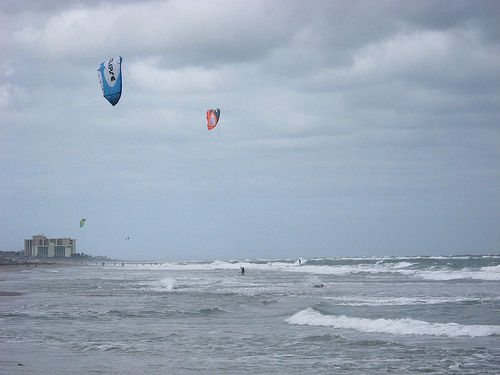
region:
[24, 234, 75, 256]
building in the background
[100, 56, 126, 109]
blue hang gliding kite in the sky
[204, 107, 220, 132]
orange and black hang gliding kite in the sky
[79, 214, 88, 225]
bright green hang gliding kite in the sky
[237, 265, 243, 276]
person hang gliding over the ocean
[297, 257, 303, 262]
person surfing on the huge waves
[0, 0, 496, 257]
the sky contains heavy clouds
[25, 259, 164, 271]
people standing near the shore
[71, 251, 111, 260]
trees near the huge building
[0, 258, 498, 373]
clean water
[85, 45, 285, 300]
large kites flying over the ocean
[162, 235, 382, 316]
person standing in a vast ocean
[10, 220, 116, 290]
large tan building near the beach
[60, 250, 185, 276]
people along the shore at a distance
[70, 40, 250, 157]
grey clouds and sky behind kites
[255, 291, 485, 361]
low wave edged in white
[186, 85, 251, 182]
red and grey kite in a triangular shape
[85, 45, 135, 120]
blue and white kite with point at bottom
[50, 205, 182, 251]
kites flying farther down beach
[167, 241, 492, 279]
horizon of grey and white waves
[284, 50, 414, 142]
part of a cloudy sky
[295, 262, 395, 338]
part of an ocean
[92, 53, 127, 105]
part of a blue kite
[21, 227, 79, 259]
section of some buildings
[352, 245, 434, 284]
part of some currents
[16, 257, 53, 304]
part of the shore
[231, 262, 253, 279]
a person in black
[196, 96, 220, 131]
part of a red kite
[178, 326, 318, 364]
part of some waves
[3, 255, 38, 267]
section of the beach side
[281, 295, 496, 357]
White waves in the ocean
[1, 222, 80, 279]
Building in the distance off the beach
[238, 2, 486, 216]
Gray clouds in the sky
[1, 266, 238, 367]
Water and waves in the ocean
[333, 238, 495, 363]
Waves in the ocean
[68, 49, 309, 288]
Four people with power kites in the ocean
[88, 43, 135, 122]
Blue and White power kite in words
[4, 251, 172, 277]
People on the beach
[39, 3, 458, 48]
Rain clouds above the ocean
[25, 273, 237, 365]
Water waves going ashore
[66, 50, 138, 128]
blue kite in the air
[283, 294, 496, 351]
white ocean wave moving right to left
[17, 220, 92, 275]
tall building on the shore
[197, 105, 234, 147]
red kite in the sky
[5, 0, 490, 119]
rain clouds above the ocean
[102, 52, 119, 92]
white circle with black writing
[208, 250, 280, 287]
person standing in the water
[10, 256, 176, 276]
people standing along the shore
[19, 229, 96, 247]
brown upper half of the building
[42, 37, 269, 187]
two kites flying over the ocean